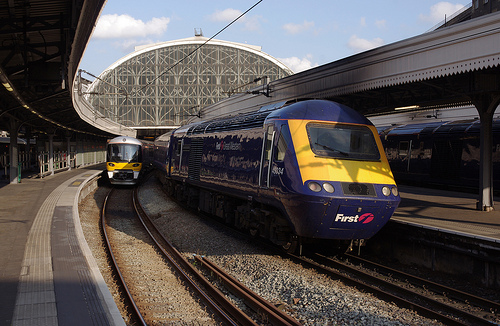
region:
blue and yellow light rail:
[195, 98, 395, 223]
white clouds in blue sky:
[265, 19, 289, 33]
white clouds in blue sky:
[275, 11, 307, 51]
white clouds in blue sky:
[328, 16, 388, 44]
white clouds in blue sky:
[114, 16, 129, 34]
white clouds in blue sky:
[161, 9, 213, 40]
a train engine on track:
[222, 80, 436, 298]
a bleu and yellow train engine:
[237, 83, 361, 223]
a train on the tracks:
[147, 76, 464, 325]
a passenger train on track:
[178, 70, 482, 295]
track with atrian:
[203, 77, 418, 262]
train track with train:
[149, 84, 432, 254]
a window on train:
[311, 115, 365, 161]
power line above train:
[135, 15, 321, 85]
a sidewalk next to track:
[14, 124, 179, 319]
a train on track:
[77, 99, 171, 268]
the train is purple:
[146, 106, 388, 248]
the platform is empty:
[8, 143, 97, 321]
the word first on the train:
[315, 200, 392, 227]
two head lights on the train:
[380, 183, 401, 201]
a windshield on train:
[307, 120, 383, 164]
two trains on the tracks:
[95, 87, 397, 264]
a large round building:
[84, 21, 306, 119]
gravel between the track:
[271, 277, 355, 310]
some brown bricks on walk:
[32, 196, 57, 221]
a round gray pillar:
[1, 125, 23, 187]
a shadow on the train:
[336, 157, 396, 185]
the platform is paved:
[5, 187, 82, 310]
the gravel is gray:
[242, 257, 330, 322]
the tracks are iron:
[145, 244, 268, 323]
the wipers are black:
[312, 137, 373, 158]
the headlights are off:
[310, 180, 400, 195]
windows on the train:
[177, 143, 277, 188]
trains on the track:
[73, 70, 415, 284]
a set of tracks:
[101, 187, 305, 320]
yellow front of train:
[288, 117, 396, 190]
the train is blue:
[146, 85, 393, 254]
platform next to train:
[0, 149, 128, 319]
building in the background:
[86, 22, 291, 149]